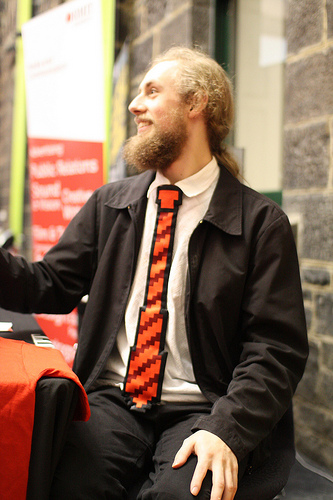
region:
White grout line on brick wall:
[282, 115, 318, 141]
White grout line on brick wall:
[305, 397, 330, 426]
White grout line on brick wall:
[309, 377, 328, 404]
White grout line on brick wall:
[312, 339, 323, 370]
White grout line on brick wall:
[305, 328, 332, 354]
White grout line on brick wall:
[306, 292, 320, 338]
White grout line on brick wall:
[297, 279, 330, 302]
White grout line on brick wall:
[298, 252, 329, 280]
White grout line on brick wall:
[283, 178, 330, 196]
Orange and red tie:
[145, 177, 171, 422]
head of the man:
[107, 40, 245, 177]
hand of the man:
[169, 432, 251, 496]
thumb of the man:
[164, 429, 201, 475]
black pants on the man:
[73, 393, 151, 488]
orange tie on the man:
[115, 188, 191, 334]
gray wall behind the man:
[294, 135, 328, 179]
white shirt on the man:
[184, 189, 223, 237]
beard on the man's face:
[122, 113, 183, 160]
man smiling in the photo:
[109, 48, 241, 172]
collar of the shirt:
[142, 153, 224, 201]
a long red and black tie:
[124, 183, 188, 415]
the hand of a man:
[170, 426, 242, 499]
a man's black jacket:
[0, 166, 313, 462]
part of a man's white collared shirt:
[96, 155, 220, 407]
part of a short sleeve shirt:
[0, 330, 92, 497]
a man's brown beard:
[117, 100, 187, 168]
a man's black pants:
[70, 381, 213, 498]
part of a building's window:
[205, 0, 280, 208]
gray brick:
[276, 61, 330, 194]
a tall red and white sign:
[20, 3, 104, 345]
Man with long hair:
[124, 45, 233, 180]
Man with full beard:
[116, 43, 230, 176]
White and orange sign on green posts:
[6, 21, 102, 219]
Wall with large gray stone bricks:
[283, 4, 331, 199]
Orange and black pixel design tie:
[125, 186, 179, 399]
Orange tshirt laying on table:
[2, 339, 53, 497]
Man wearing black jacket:
[72, 57, 238, 372]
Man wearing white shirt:
[81, 43, 244, 348]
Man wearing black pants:
[67, 402, 228, 496]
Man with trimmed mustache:
[122, 45, 232, 176]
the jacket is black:
[61, 165, 276, 466]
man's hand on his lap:
[167, 387, 267, 495]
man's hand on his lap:
[176, 418, 234, 497]